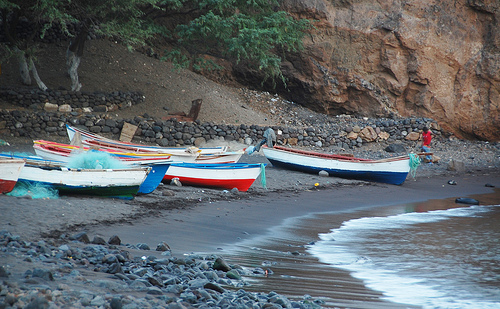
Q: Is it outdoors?
A: Yes, it is outdoors.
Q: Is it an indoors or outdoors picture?
A: It is outdoors.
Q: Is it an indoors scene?
A: No, it is outdoors.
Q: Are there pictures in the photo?
A: No, there are no pictures.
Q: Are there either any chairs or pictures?
A: No, there are no pictures or chairs.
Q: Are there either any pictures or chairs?
A: No, there are no pictures or chairs.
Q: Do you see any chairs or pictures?
A: No, there are no pictures or chairs.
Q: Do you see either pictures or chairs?
A: No, there are no pictures or chairs.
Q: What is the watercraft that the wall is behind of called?
A: The watercraft is boats.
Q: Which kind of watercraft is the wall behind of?
A: The wall is behind the boats.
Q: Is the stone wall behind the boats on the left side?
A: Yes, the wall is behind the boats.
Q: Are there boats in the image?
A: Yes, there is a boat.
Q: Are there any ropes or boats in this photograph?
A: Yes, there is a boat.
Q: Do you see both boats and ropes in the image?
A: No, there is a boat but no ropes.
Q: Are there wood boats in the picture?
A: Yes, there is a wood boat.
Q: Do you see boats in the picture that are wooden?
A: Yes, there is a boat that is wooden.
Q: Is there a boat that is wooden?
A: Yes, there is a boat that is wooden.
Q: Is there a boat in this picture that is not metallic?
A: Yes, there is a wooden boat.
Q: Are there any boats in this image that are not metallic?
A: Yes, there is a wooden boat.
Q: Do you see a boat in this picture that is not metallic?
A: Yes, there is a wooden boat.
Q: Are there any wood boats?
A: Yes, there is a boat that is made of wood.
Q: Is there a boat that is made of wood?
A: Yes, there is a boat that is made of wood.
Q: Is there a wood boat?
A: Yes, there is a boat that is made of wood.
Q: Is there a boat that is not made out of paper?
A: Yes, there is a boat that is made of wood.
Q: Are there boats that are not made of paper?
A: Yes, there is a boat that is made of wood.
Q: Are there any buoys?
A: No, there are no buoys.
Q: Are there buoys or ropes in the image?
A: No, there are no buoys or ropes.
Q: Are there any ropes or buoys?
A: No, there are no buoys or ropes.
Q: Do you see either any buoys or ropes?
A: No, there are no buoys or ropes.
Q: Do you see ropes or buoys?
A: No, there are no buoys or ropes.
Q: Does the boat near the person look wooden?
A: Yes, the boat is wooden.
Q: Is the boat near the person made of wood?
A: Yes, the boat is made of wood.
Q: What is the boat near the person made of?
A: The boat is made of wood.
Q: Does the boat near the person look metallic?
A: No, the boat is wooden.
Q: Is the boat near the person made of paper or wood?
A: The boat is made of wood.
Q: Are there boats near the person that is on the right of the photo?
A: Yes, there is a boat near the person.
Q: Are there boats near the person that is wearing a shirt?
A: Yes, there is a boat near the person.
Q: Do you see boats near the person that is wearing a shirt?
A: Yes, there is a boat near the person.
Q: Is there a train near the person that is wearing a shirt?
A: No, there is a boat near the person.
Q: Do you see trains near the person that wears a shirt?
A: No, there is a boat near the person.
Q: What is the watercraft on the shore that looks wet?
A: The watercraft is a boat.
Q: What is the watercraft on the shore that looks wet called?
A: The watercraft is a boat.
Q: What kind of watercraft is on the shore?
A: The watercraft is a boat.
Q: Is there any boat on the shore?
A: Yes, there is a boat on the shore.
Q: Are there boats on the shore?
A: Yes, there is a boat on the shore.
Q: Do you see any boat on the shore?
A: Yes, there is a boat on the shore.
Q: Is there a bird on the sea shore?
A: No, there is a boat on the sea shore.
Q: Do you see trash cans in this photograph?
A: No, there are no trash cans.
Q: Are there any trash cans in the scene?
A: No, there are no trash cans.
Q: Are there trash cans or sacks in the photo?
A: No, there are no trash cans or sacks.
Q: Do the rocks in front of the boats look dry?
A: No, the rocks are wet.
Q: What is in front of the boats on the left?
A: The rocks are in front of the boats.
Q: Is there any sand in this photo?
A: Yes, there is sand.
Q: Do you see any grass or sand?
A: Yes, there is sand.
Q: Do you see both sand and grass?
A: No, there is sand but no grass.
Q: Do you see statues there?
A: No, there are no statues.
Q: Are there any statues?
A: No, there are no statues.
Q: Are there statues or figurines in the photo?
A: No, there are no statues or figurines.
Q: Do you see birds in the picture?
A: No, there are no birds.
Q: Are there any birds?
A: No, there are no birds.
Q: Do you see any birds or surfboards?
A: No, there are no birds or surfboards.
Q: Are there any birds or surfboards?
A: No, there are no birds or surfboards.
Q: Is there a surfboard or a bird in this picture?
A: No, there are no birds or surfboards.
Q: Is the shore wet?
A: Yes, the shore is wet.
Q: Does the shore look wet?
A: Yes, the shore is wet.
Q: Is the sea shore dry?
A: No, the sea shore is wet.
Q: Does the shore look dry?
A: No, the shore is wet.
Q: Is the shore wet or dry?
A: The shore is wet.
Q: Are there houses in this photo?
A: No, there are no houses.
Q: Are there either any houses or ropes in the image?
A: No, there are no houses or ropes.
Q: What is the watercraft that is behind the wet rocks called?
A: The watercraft is boats.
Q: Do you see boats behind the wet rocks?
A: Yes, there are boats behind the rocks.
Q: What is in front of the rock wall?
A: The boats are in front of the wall.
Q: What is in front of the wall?
A: The boats are in front of the wall.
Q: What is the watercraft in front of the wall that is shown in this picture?
A: The watercraft is boats.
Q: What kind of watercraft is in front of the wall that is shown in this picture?
A: The watercraft is boats.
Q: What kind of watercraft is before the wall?
A: The watercraft is boats.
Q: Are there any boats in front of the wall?
A: Yes, there are boats in front of the wall.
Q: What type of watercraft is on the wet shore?
A: The watercraft is boats.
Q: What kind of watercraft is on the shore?
A: The watercraft is boats.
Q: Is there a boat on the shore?
A: Yes, there are boats on the shore.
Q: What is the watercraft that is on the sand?
A: The watercraft is boats.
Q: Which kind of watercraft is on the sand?
A: The watercraft is boats.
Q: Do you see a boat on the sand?
A: Yes, there are boats on the sand.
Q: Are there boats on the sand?
A: Yes, there are boats on the sand.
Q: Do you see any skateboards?
A: No, there are no skateboards.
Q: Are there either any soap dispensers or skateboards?
A: No, there are no skateboards or soap dispensers.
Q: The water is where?
A: The water is on the shore.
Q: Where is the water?
A: The water is on the shore.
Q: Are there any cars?
A: No, there are no cars.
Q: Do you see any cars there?
A: No, there are no cars.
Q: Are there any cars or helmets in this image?
A: No, there are no cars or helmets.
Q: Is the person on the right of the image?
A: Yes, the person is on the right of the image.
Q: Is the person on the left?
A: No, the person is on the right of the image.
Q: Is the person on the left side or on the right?
A: The person is on the right of the image.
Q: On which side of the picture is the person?
A: The person is on the right of the image.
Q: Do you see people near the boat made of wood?
A: Yes, there is a person near the boat.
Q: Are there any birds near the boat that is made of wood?
A: No, there is a person near the boat.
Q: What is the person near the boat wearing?
A: The person is wearing a shirt.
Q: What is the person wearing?
A: The person is wearing a shirt.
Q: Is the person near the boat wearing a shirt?
A: Yes, the person is wearing a shirt.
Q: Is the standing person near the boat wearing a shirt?
A: Yes, the person is wearing a shirt.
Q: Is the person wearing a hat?
A: No, the person is wearing a shirt.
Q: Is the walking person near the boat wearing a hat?
A: No, the person is wearing a shirt.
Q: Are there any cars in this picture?
A: No, there are no cars.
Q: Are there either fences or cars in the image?
A: No, there are no cars or fences.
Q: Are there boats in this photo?
A: Yes, there is a boat.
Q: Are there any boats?
A: Yes, there is a boat.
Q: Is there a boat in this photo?
A: Yes, there is a boat.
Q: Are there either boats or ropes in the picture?
A: Yes, there is a boat.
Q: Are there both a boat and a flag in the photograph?
A: No, there is a boat but no flags.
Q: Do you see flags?
A: No, there are no flags.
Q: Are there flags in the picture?
A: No, there are no flags.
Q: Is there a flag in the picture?
A: No, there are no flags.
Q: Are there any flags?
A: No, there are no flags.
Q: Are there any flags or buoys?
A: No, there are no flags or buoys.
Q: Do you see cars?
A: No, there are no cars.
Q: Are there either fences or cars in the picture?
A: No, there are no cars or fences.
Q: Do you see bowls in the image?
A: No, there are no bowls.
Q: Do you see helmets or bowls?
A: No, there are no bowls or helmets.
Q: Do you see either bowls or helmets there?
A: No, there are no bowls or helmets.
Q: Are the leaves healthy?
A: Yes, the leaves are healthy.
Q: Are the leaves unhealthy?
A: No, the leaves are healthy.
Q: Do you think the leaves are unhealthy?
A: No, the leaves are healthy.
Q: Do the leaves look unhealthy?
A: No, the leaves are healthy.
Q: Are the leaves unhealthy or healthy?
A: The leaves are healthy.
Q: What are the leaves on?
A: The leaves are on the tree.